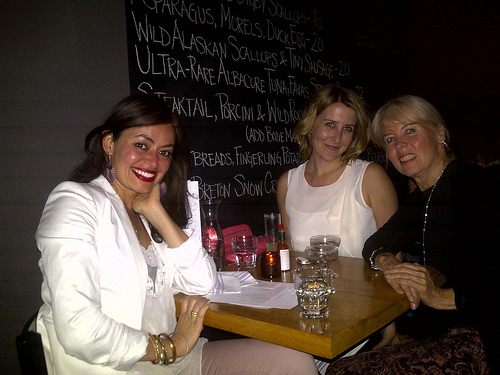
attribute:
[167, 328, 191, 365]
bracelet — metal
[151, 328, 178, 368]
bracelets — gold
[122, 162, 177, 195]
lips — lipstick-red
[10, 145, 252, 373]
blazer — white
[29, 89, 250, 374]
woman — one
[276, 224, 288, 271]
tabasco sauce — bottle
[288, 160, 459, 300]
top — sleeveless, white, plain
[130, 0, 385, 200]
chalk — white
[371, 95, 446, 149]
hair — blonde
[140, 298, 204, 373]
bracelets — bangle, bunch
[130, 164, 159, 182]
teeth — white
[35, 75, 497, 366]
woman — one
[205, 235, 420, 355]
table — small, wooden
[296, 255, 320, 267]
cellphone — white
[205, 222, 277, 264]
wallet — pink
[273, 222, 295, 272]
sauce — tabasco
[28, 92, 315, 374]
woman — haired, dark, pretty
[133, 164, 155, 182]
lipstick — red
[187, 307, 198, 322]
rings — gold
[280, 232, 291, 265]
bottle — small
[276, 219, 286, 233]
cap — red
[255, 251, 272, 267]
holder — candle, glass, small, red, frosted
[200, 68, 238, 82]
chalk — white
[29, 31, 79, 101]
wall — gray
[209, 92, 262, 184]
board — black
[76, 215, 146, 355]
jacket — white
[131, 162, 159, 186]
lips — red